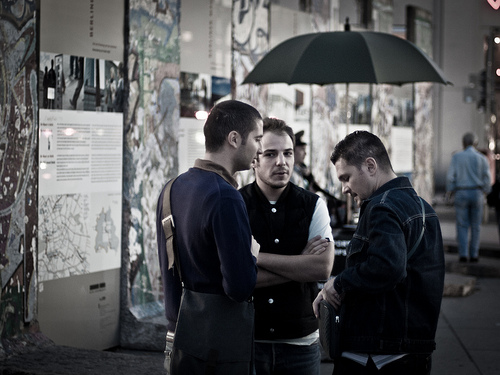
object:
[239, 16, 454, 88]
umbrella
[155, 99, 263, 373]
man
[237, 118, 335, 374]
man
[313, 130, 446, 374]
man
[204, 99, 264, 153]
hair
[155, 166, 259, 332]
sweater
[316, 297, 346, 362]
bag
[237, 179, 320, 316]
vest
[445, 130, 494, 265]
person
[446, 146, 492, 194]
shirt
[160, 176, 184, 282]
strap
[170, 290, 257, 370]
bag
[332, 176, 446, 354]
jacket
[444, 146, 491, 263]
clothing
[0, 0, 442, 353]
wall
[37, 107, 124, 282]
picture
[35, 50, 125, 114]
picture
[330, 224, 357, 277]
table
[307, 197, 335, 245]
shirt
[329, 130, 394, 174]
hair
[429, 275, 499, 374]
sidewalk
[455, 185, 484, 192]
belt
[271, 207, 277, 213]
button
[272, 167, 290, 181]
mustache